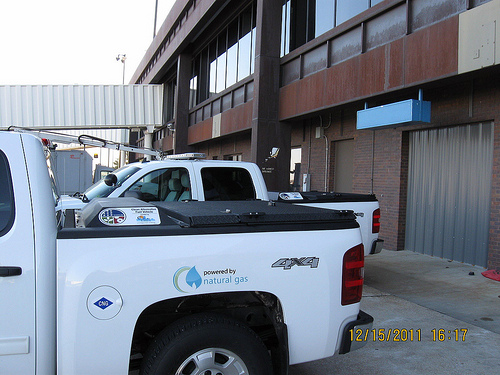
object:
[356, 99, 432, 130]
box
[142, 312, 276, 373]
tire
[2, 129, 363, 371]
truck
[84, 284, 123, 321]
cover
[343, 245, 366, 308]
light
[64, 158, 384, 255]
truck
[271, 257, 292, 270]
numbers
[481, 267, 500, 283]
rag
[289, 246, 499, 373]
ground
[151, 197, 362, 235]
cover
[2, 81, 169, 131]
walkway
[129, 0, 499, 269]
building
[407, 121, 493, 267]
door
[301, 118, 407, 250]
wall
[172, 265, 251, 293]
logo